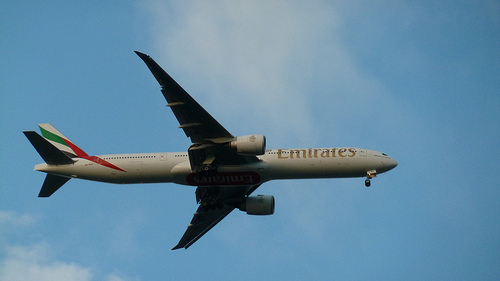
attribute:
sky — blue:
[10, 9, 485, 266]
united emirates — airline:
[267, 146, 357, 159]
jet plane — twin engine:
[21, 47, 398, 254]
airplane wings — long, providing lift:
[133, 47, 261, 255]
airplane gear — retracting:
[362, 170, 373, 189]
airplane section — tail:
[20, 120, 83, 199]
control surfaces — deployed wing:
[167, 90, 199, 135]